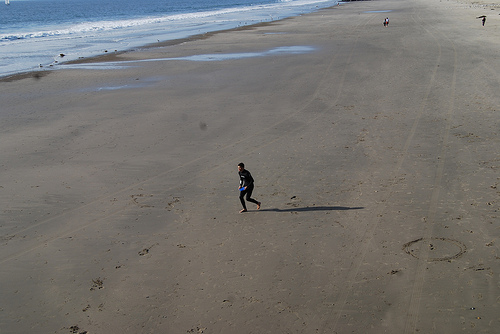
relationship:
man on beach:
[238, 152, 253, 210] [267, 159, 300, 182]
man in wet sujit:
[238, 152, 253, 210] [233, 174, 265, 216]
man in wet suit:
[238, 152, 253, 210] [234, 174, 261, 209]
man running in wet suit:
[238, 152, 253, 210] [234, 174, 261, 209]